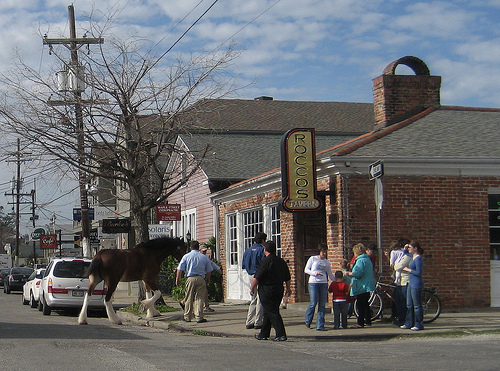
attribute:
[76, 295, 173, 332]
hooves — white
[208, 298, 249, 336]
sidewalk — paved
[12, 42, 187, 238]
tree — bare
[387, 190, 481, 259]
wall — bricked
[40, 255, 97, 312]
van — white, parked